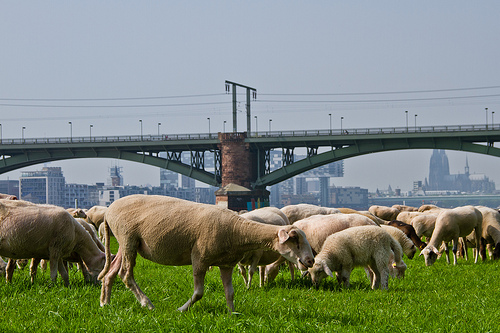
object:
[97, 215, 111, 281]
tail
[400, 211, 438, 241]
sheep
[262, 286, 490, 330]
field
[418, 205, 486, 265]
animal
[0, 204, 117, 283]
animal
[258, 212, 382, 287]
animal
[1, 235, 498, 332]
grass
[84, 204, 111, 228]
sheep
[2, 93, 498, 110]
power cable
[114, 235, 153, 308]
leg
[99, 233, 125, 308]
leg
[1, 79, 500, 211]
bridge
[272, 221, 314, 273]
head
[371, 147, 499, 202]
buildings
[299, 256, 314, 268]
nose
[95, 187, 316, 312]
animal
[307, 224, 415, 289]
animal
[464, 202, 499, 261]
animal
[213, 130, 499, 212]
support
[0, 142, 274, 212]
support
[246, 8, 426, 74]
sky